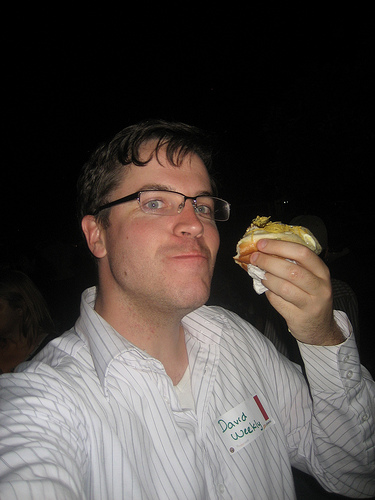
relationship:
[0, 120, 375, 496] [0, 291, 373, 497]
man wearing shirt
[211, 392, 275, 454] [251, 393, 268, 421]
name tag has line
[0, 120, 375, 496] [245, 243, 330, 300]
man has hand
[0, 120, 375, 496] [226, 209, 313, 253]
man holding food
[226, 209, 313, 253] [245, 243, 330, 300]
food in hand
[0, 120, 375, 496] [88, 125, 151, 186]
man has hair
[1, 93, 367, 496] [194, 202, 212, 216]
man has eye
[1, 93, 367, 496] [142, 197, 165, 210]
man has eye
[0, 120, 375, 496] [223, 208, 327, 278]
man eating hotdog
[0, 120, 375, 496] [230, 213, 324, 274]
man eating hot dog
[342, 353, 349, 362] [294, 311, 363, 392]
button is on cuff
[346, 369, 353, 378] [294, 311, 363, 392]
button is on cuff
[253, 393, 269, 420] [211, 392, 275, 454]
line is on name tag